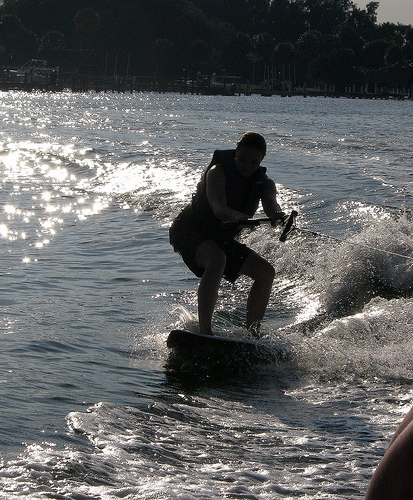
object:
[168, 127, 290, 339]
man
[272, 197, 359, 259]
pulled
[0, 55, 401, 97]
boats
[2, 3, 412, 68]
shoreline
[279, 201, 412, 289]
ski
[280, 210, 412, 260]
line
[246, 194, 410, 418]
wake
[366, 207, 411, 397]
engine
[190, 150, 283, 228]
vest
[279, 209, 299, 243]
handle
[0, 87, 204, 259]
sunlight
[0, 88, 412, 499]
water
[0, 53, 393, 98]
dock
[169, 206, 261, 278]
shorts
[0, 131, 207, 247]
waves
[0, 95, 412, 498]
sea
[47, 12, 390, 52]
distance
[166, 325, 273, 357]
surfboard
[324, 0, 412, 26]
sky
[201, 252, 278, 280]
knees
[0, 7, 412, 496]
season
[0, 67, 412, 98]
docks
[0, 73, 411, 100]
dock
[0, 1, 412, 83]
trees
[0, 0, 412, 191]
background